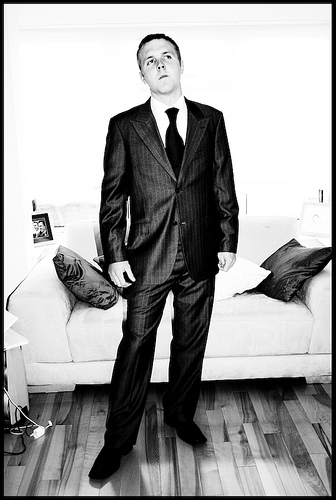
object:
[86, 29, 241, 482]
man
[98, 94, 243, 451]
suit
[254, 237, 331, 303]
pillow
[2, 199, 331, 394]
couch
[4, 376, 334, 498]
floor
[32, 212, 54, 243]
picture frame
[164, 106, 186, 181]
tie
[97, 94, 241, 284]
jacket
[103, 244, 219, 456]
pants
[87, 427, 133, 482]
shoes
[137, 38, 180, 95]
face